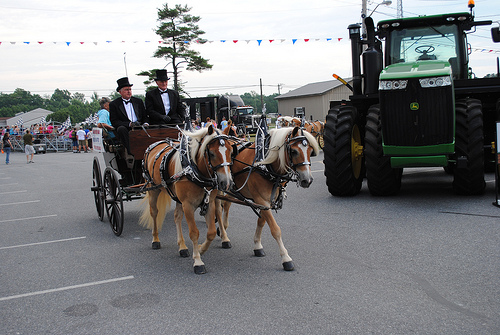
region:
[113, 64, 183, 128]
Two men wearing top hats.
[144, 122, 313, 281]
Two brown horses pull carriage.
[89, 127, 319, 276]
Brown carriage with two horses.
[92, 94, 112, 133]
Man in light blue shirt riding in carriage.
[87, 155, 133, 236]
Two wheels on the carriage.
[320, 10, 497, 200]
Green tractor parked in lot.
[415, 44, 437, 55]
Steering wheel of tractor.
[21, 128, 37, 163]
Man in dark shirt and beige cargo shorts.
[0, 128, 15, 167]
Person in dark shirt and blue pants.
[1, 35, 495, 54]
Blue, red and white pennant banner.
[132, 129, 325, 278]
the two horses on the road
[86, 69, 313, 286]
the horses pulling the wagon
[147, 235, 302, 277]
the black hooves of the horse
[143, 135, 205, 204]
the black harness on the horses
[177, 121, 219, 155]
the long white hair on the horse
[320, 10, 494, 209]
a green john deer tractor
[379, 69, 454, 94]
the head lights on the front of the tractor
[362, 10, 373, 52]
the tractors black smoke exhuast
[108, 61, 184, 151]
the men in suits on the wagon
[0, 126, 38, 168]
people standing in the parking lot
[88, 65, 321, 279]
Two horses pulling a carriage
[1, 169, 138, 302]
White lines on the pavement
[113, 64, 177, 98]
Two black top hats on men's heads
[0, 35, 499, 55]
A row of many flags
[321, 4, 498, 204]
A big green tractor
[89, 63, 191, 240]
Two men riding a carriage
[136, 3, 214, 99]
A tall green tree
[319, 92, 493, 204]
Large black round tires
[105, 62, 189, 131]
Two men wearing suits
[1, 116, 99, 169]
Crowd of people in the background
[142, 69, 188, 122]
Man wearing top hat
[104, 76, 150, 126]
Man wearing top hat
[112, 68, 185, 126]
Two men wearing top hats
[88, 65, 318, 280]
Two horses driving a carriage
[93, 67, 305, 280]
Two men driving a carriage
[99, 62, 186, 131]
Two men wearing tuxedos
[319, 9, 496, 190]
Green Deere tractor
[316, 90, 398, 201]
Very large wheels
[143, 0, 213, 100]
Large tree with green leaves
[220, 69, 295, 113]
Power lines on wood pole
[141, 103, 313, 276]
horses pulling a buggy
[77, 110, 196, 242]
buggy drawn by two horses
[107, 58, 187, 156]
two men on a buggy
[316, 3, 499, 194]
big green tractor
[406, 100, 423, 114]
john deere logo on the tractor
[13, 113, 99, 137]
line of black and white flags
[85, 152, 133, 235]
wheels on one side of the buggy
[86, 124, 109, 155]
white sign on side of buggy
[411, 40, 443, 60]
steering wheel of the tractor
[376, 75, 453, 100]
headlights in the front of the tractor